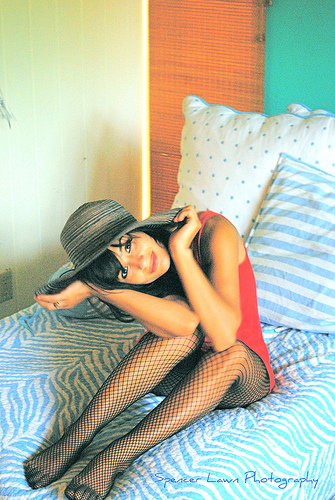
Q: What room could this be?
A: It is a bedroom.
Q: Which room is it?
A: It is a bedroom.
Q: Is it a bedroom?
A: Yes, it is a bedroom.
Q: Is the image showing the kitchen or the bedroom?
A: It is showing the bedroom.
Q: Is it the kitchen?
A: No, it is the bedroom.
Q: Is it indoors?
A: Yes, it is indoors.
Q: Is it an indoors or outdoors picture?
A: It is indoors.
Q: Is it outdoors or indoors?
A: It is indoors.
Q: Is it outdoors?
A: No, it is indoors.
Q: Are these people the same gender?
A: Yes, all the people are female.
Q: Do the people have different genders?
A: No, all the people are female.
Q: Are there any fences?
A: No, there are no fences.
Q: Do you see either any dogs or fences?
A: No, there are no fences or dogs.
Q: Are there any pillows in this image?
A: Yes, there is a pillow.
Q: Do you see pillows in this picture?
A: Yes, there is a pillow.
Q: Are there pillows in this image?
A: Yes, there is a pillow.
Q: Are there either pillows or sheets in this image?
A: Yes, there is a pillow.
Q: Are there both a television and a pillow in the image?
A: No, there is a pillow but no televisions.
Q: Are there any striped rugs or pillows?
A: Yes, there is a striped pillow.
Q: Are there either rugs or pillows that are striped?
A: Yes, the pillow is striped.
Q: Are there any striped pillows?
A: Yes, there is a striped pillow.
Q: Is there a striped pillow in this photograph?
A: Yes, there is a striped pillow.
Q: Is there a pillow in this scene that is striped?
A: Yes, there is a pillow that is striped.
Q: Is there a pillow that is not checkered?
A: Yes, there is a striped pillow.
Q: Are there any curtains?
A: No, there are no curtains.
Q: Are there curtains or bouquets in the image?
A: No, there are no curtains or bouquets.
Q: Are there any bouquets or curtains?
A: No, there are no curtains or bouquets.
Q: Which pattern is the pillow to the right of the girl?
A: The pillow is striped.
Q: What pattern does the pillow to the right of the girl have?
A: The pillow has striped pattern.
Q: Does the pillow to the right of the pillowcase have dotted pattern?
A: No, the pillow is striped.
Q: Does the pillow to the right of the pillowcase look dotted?
A: No, the pillow is striped.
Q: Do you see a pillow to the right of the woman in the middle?
A: Yes, there is a pillow to the right of the woman.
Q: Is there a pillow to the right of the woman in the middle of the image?
A: Yes, there is a pillow to the right of the woman.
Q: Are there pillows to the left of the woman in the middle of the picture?
A: No, the pillow is to the right of the woman.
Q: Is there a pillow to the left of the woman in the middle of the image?
A: No, the pillow is to the right of the woman.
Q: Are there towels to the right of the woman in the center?
A: No, there is a pillow to the right of the woman.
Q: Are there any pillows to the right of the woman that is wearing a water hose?
A: Yes, there is a pillow to the right of the woman.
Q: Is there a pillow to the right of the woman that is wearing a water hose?
A: Yes, there is a pillow to the right of the woman.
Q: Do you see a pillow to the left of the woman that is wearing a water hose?
A: No, the pillow is to the right of the woman.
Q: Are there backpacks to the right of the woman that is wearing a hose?
A: No, there is a pillow to the right of the woman.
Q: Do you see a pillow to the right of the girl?
A: Yes, there is a pillow to the right of the girl.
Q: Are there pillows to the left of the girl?
A: No, the pillow is to the right of the girl.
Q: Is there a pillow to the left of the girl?
A: No, the pillow is to the right of the girl.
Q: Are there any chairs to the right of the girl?
A: No, there is a pillow to the right of the girl.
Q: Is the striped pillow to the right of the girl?
A: Yes, the pillow is to the right of the girl.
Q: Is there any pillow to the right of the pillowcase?
A: Yes, there is a pillow to the right of the pillowcase.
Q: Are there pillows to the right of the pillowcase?
A: Yes, there is a pillow to the right of the pillowcase.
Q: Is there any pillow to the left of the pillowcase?
A: No, the pillow is to the right of the pillowcase.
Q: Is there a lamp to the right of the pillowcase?
A: No, there is a pillow to the right of the pillowcase.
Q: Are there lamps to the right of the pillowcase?
A: No, there is a pillow to the right of the pillowcase.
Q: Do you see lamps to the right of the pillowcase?
A: No, there is a pillow to the right of the pillowcase.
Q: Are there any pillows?
A: Yes, there is a pillow.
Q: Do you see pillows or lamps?
A: Yes, there is a pillow.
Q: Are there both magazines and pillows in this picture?
A: No, there is a pillow but no magazines.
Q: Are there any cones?
A: No, there are no cones.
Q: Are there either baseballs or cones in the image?
A: No, there are no cones or baseballs.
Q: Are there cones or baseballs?
A: No, there are no cones or baseballs.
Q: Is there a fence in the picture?
A: No, there are no fences.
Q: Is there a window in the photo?
A: Yes, there is a window.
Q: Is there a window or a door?
A: Yes, there is a window.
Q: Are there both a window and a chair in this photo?
A: No, there is a window but no chairs.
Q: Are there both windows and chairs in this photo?
A: No, there is a window but no chairs.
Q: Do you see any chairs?
A: No, there are no chairs.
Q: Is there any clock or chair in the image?
A: No, there are no chairs or clocks.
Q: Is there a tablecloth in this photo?
A: No, there are no tablecloths.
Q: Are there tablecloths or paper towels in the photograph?
A: No, there are no tablecloths or paper towels.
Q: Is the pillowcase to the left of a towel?
A: No, the pillowcase is to the left of the pillow.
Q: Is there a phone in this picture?
A: No, there are no phones.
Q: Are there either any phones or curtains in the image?
A: No, there are no phones or curtains.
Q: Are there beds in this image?
A: Yes, there is a bed.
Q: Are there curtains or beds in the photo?
A: Yes, there is a bed.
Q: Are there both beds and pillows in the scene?
A: Yes, there are both a bed and a pillow.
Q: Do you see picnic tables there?
A: No, there are no picnic tables.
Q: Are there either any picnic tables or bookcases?
A: No, there are no picnic tables or bookcases.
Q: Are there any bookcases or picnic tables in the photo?
A: No, there are no picnic tables or bookcases.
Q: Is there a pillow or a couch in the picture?
A: Yes, there is a pillow.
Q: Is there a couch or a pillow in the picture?
A: Yes, there is a pillow.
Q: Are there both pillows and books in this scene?
A: No, there is a pillow but no books.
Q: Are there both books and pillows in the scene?
A: No, there is a pillow but no books.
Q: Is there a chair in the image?
A: No, there are no chairs.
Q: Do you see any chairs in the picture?
A: No, there are no chairs.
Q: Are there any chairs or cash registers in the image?
A: No, there are no chairs or cash registers.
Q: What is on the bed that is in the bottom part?
A: The pillow is on the bed.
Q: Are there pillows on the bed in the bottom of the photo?
A: Yes, there is a pillow on the bed.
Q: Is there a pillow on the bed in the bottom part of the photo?
A: Yes, there is a pillow on the bed.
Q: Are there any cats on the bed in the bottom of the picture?
A: No, there is a pillow on the bed.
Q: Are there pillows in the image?
A: Yes, there is a pillow.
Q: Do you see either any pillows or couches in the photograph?
A: Yes, there is a pillow.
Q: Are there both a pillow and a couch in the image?
A: No, there is a pillow but no couches.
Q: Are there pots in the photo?
A: No, there are no pots.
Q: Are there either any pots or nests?
A: No, there are no pots or nests.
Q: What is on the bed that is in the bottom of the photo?
A: The pillow is on the bed.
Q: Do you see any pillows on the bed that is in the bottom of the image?
A: Yes, there is a pillow on the bed.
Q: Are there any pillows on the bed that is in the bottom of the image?
A: Yes, there is a pillow on the bed.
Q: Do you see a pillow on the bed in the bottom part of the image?
A: Yes, there is a pillow on the bed.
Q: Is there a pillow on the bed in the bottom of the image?
A: Yes, there is a pillow on the bed.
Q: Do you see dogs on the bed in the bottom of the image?
A: No, there is a pillow on the bed.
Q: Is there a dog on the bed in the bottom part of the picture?
A: No, there is a pillow on the bed.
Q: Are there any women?
A: Yes, there is a woman.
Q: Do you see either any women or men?
A: Yes, there is a woman.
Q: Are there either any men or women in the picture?
A: Yes, there is a woman.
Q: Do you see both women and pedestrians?
A: No, there is a woman but no pedestrians.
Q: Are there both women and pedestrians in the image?
A: No, there is a woman but no pedestrians.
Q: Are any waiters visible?
A: No, there are no waiters.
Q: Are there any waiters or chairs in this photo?
A: No, there are no waiters or chairs.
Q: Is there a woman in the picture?
A: Yes, there is a woman.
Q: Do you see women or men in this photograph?
A: Yes, there is a woman.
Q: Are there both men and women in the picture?
A: No, there is a woman but no men.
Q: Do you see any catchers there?
A: No, there are no catchers.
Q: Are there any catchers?
A: No, there are no catchers.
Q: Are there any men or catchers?
A: No, there are no catchers or men.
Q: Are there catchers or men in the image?
A: No, there are no catchers or men.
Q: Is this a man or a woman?
A: This is a woman.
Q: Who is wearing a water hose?
A: The woman is wearing a water hose.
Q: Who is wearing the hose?
A: The woman is wearing a water hose.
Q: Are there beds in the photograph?
A: Yes, there is a bed.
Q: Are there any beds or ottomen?
A: Yes, there is a bed.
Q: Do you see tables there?
A: No, there are no tables.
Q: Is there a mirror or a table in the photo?
A: No, there are no tables or mirrors.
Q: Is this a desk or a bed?
A: This is a bed.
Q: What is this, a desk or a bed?
A: This is a bed.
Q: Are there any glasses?
A: No, there are no glasses.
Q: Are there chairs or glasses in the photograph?
A: No, there are no glasses or chairs.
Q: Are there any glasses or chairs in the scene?
A: No, there are no glasses or chairs.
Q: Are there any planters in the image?
A: No, there are no planters.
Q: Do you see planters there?
A: No, there are no planters.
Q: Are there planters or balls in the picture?
A: No, there are no planters or balls.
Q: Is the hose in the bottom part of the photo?
A: Yes, the hose is in the bottom of the image.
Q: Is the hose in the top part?
A: No, the hose is in the bottom of the image.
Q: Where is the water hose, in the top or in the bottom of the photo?
A: The water hose is in the bottom of the image.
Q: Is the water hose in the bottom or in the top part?
A: The water hose is in the bottom of the image.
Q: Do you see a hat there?
A: Yes, there is a hat.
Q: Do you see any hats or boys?
A: Yes, there is a hat.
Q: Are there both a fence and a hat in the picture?
A: No, there is a hat but no fences.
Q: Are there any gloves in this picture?
A: No, there are no gloves.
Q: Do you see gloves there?
A: No, there are no gloves.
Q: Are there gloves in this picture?
A: No, there are no gloves.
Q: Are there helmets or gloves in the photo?
A: No, there are no gloves or helmets.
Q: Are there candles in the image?
A: No, there are no candles.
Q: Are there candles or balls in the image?
A: No, there are no candles or balls.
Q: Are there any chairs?
A: No, there are no chairs.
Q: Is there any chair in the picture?
A: No, there are no chairs.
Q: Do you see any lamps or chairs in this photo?
A: No, there are no chairs or lamps.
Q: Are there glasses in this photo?
A: No, there are no glasses.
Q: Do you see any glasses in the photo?
A: No, there are no glasses.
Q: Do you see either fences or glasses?
A: No, there are no glasses or fences.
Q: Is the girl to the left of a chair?
A: No, the girl is to the left of the pillow.